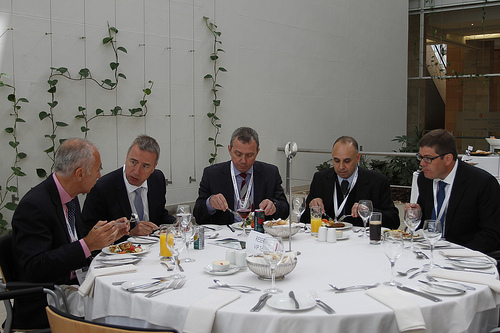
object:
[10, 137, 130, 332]
man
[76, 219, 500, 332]
table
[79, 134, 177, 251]
man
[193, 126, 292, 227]
man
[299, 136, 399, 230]
man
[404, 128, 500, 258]
man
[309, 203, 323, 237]
glass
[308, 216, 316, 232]
orange juice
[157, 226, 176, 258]
glass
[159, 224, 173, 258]
orange juice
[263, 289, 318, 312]
plate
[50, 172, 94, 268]
shirt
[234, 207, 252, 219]
wine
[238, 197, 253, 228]
glass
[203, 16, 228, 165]
ivy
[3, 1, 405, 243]
wall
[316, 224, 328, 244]
shaker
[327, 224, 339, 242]
shaker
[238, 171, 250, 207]
tie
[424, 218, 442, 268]
glass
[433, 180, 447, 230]
tie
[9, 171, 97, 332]
suit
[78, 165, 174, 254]
suit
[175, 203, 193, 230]
glass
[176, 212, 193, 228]
water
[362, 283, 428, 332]
napkin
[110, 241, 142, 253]
food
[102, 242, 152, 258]
plate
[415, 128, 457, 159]
hair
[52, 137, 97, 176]
hair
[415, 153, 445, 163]
glasses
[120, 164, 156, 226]
shirt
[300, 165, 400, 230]
jacket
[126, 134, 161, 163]
hair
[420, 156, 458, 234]
shirt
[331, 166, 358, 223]
medal